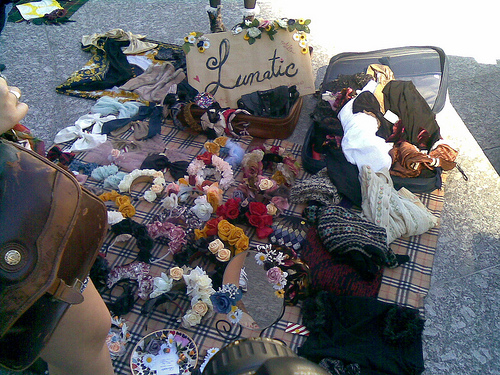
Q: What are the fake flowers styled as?
A: Roses.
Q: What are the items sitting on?
A: Blanket.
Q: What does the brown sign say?
A: Lunatic.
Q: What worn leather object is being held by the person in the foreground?
A: Purse.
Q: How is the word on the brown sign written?
A: In cursive.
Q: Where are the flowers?
A: On a blanket.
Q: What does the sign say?
A: Lunatic.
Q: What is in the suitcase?
A: Clothes.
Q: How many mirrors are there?
A: One.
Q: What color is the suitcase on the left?
A: Brown.